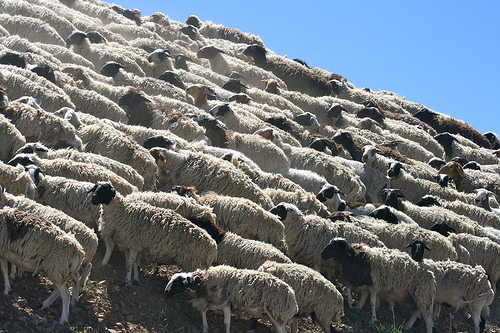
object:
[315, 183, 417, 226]
sheep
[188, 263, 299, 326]
wool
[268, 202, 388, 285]
sheep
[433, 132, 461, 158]
black head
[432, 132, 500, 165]
sheep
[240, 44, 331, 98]
sheep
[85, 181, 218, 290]
sheep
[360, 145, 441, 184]
sheep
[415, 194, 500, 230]
sheep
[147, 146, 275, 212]
sheep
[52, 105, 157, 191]
sheep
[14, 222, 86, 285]
back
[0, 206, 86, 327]
sheep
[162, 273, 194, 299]
head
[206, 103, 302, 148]
sheep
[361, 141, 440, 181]
animal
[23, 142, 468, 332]
hill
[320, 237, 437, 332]
sheep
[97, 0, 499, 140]
blue sky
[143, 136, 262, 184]
sheep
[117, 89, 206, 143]
sheep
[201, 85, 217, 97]
ear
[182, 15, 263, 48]
sheep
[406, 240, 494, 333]
sheep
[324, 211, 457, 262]
sheep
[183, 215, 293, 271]
sheep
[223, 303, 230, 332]
leg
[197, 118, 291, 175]
sheep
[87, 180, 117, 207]
head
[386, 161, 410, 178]
head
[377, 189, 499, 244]
sheep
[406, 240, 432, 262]
head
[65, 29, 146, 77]
sheep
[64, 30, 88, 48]
head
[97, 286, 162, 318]
dirt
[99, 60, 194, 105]
spot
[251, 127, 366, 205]
sheep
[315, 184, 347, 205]
face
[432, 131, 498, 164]
spots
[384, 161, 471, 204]
sheep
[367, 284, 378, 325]
leg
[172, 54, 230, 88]
sheep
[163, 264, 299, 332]
sheep